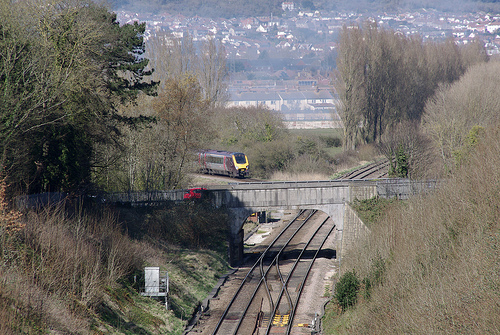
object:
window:
[235, 155, 247, 165]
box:
[144, 266, 160, 293]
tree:
[1, 5, 92, 209]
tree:
[60, 0, 150, 209]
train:
[174, 186, 204, 202]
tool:
[271, 312, 291, 326]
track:
[185, 132, 465, 331]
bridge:
[73, 181, 457, 213]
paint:
[184, 187, 204, 199]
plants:
[390, 246, 442, 320]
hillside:
[242, 47, 301, 78]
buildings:
[144, 13, 471, 83]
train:
[204, 146, 254, 176]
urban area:
[112, 12, 499, 60]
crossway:
[228, 167, 334, 239]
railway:
[191, 151, 409, 333]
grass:
[353, 72, 496, 333]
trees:
[320, 3, 487, 194]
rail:
[193, 204, 369, 333]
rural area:
[3, 1, 496, 331]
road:
[225, 169, 343, 214]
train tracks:
[217, 217, 327, 333]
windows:
[201, 154, 226, 164]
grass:
[158, 246, 221, 303]